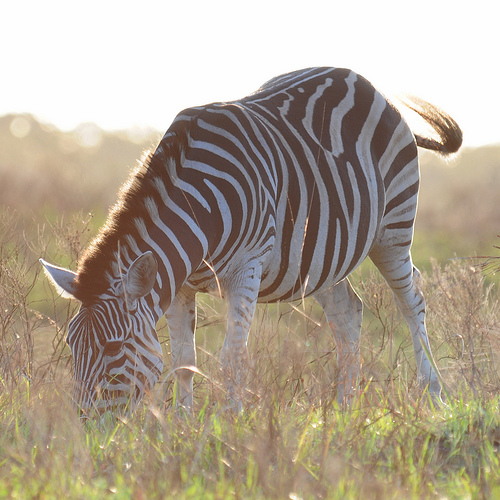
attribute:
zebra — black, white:
[59, 101, 441, 382]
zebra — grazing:
[29, 58, 466, 463]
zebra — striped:
[28, 19, 481, 437]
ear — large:
[122, 246, 157, 314]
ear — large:
[33, 255, 80, 298]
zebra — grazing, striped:
[50, 76, 475, 417]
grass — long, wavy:
[290, 380, 465, 477]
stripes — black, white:
[227, 120, 382, 249]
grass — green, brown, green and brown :
[0, 214, 497, 498]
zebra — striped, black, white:
[37, 65, 462, 422]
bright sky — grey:
[1, 56, 498, 131]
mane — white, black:
[88, 167, 173, 257]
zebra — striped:
[140, 59, 463, 420]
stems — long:
[375, 319, 391, 356]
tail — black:
[403, 96, 466, 156]